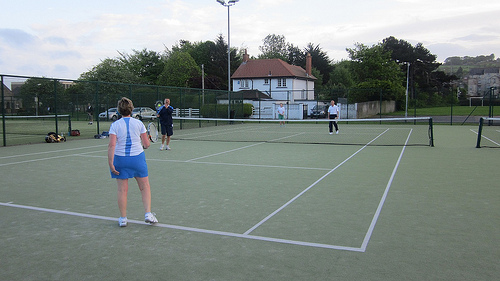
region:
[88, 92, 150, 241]
a woman wearing a blue and white uniform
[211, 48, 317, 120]
a white house with two chimneys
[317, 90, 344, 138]
a man wearing a white shirt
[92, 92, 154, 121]
two cars in a parking lot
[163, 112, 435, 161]
a tennis net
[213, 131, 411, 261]
white lines painted on a tennis court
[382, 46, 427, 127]
a tall street light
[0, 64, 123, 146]
a tall green chain link fence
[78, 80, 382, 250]
three people on a tennis court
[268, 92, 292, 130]
a person wearing green shorts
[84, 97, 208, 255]
person in blue shorts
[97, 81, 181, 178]
person in white and blue shirt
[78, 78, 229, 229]
people on tennis court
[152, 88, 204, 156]
man in black outfit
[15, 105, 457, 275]
woman on tennis court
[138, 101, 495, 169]
two tennis nets visible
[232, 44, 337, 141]
white house in photograph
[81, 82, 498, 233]
three people on tennis court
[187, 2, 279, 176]
street lamp in photograph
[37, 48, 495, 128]
trees visible in photo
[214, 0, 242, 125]
Metal light pole behind a tennis court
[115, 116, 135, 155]
Blue stripe down a woman's white shirt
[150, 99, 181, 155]
Man standing at a tennis net with his hands behind his back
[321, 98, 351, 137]
Man with a white shirt walking toward a tennis net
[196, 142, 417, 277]
White lines on a green tennis court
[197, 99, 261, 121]
Green shrubs behind a tennis court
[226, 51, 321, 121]
Two story house behind a tennis court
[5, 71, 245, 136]
Fence separating tennis courts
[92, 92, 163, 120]
Two cars parked in a parking lot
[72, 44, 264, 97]
Trees above a fence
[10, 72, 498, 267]
tennis courts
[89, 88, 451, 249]
people are playing tennis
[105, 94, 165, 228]
a woman wearing white and blue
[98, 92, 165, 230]
the woman holds a tennis racket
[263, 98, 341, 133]
two people are on the far side of the court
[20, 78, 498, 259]
the tennis courts are green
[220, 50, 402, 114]
a house with a fenced yard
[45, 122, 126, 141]
bags are on the ground to the left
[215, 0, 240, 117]
a tall light post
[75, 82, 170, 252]
woman playing tennis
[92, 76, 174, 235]
woman with short brown hair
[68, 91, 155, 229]
woman wearing white and blue pullover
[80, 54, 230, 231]
woman wearing blue shorts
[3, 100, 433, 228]
large grass tennis court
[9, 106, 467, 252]
boundary lines on a tennis court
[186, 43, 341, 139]
beautiful two story home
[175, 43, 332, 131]
beautiful two story home with red roof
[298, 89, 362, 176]
man wearing white pullover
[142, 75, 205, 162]
man wearing a black pullover